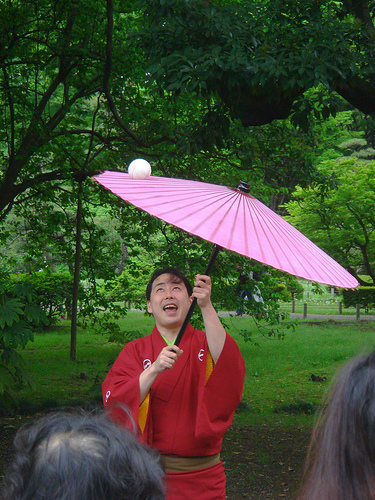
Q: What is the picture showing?
A: It is showing a park.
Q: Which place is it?
A: It is a park.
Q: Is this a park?
A: Yes, it is a park.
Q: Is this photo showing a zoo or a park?
A: It is showing a park.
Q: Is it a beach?
A: No, it is a park.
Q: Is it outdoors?
A: Yes, it is outdoors.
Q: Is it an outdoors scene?
A: Yes, it is outdoors.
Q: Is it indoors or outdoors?
A: It is outdoors.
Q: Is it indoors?
A: No, it is outdoors.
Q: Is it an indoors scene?
A: No, it is outdoors.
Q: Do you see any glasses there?
A: No, there are no glasses.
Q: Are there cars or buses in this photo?
A: No, there are no cars or buses.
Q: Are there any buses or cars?
A: No, there are no cars or buses.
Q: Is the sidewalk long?
A: Yes, the sidewalk is long.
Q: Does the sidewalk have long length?
A: Yes, the sidewalk is long.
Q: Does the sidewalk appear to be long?
A: Yes, the sidewalk is long.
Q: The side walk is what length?
A: The side walk is long.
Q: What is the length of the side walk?
A: The side walk is long.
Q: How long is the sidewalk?
A: The sidewalk is long.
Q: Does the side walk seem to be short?
A: No, the side walk is long.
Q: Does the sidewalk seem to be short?
A: No, the sidewalk is long.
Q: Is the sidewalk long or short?
A: The sidewalk is long.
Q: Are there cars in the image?
A: No, there are no cars.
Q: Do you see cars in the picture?
A: No, there are no cars.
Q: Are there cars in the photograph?
A: No, there are no cars.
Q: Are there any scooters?
A: No, there are no scooters.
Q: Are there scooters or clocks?
A: No, there are no scooters or clocks.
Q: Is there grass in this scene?
A: Yes, there is grass.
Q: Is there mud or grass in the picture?
A: Yes, there is grass.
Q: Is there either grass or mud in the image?
A: Yes, there is grass.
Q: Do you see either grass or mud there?
A: Yes, there is grass.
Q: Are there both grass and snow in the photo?
A: No, there is grass but no snow.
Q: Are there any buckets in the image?
A: No, there are no buckets.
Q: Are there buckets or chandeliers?
A: No, there are no buckets or chandeliers.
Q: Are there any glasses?
A: No, there are no glasses.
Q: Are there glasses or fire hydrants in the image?
A: No, there are no glasses or fire hydrants.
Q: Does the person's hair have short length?
A: Yes, the hair is short.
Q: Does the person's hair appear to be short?
A: Yes, the hair is short.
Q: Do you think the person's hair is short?
A: Yes, the hair is short.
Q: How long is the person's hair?
A: The hair is short.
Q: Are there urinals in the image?
A: No, there are no urinals.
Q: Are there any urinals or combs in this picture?
A: No, there are no urinals or combs.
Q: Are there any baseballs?
A: Yes, there is a baseball.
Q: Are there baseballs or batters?
A: Yes, there is a baseball.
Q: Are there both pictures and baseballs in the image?
A: No, there is a baseball but no pictures.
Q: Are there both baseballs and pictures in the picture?
A: No, there is a baseball but no pictures.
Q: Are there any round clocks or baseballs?
A: Yes, there is a round baseball.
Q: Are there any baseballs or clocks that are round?
A: Yes, the baseball is round.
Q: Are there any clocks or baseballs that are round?
A: Yes, the baseball is round.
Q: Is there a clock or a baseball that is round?
A: Yes, the baseball is round.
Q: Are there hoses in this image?
A: No, there are no hoses.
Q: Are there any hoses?
A: No, there are no hoses.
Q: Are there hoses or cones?
A: No, there are no hoses or cones.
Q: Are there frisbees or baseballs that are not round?
A: No, there is a baseball but it is round.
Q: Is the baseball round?
A: Yes, the baseball is round.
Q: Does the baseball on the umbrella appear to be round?
A: Yes, the baseball is round.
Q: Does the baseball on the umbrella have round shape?
A: Yes, the baseball is round.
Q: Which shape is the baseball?
A: The baseball is round.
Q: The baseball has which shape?
A: The baseball is round.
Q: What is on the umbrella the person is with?
A: The baseball is on the umbrella.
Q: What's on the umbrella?
A: The baseball is on the umbrella.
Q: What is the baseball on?
A: The baseball is on the umbrella.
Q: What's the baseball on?
A: The baseball is on the umbrella.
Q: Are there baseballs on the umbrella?
A: Yes, there is a baseball on the umbrella.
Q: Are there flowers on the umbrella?
A: No, there is a baseball on the umbrella.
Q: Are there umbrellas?
A: Yes, there is an umbrella.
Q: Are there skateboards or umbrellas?
A: Yes, there is an umbrella.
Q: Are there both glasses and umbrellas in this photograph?
A: No, there is an umbrella but no glasses.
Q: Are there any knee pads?
A: No, there are no knee pads.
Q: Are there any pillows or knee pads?
A: No, there are no knee pads or pillows.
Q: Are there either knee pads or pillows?
A: No, there are no knee pads or pillows.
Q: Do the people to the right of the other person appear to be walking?
A: Yes, the people are walking.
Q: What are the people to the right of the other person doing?
A: The people are walking.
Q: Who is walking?
A: The people are walking.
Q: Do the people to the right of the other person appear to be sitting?
A: No, the people are walking.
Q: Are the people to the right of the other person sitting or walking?
A: The people are walking.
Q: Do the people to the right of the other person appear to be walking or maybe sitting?
A: The people are walking.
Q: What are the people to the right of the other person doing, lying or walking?
A: The people are walking.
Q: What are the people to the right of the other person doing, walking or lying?
A: The people are walking.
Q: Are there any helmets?
A: No, there are no helmets.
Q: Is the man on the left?
A: Yes, the man is on the left of the image.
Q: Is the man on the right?
A: No, the man is on the left of the image.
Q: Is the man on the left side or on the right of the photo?
A: The man is on the left of the image.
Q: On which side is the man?
A: The man is on the left of the image.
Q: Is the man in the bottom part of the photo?
A: Yes, the man is in the bottom of the image.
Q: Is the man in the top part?
A: No, the man is in the bottom of the image.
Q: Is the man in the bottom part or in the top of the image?
A: The man is in the bottom of the image.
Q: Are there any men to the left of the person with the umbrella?
A: Yes, there is a man to the left of the person.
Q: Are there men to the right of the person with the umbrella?
A: No, the man is to the left of the person.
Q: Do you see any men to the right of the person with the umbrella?
A: No, the man is to the left of the person.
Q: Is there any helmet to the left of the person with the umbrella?
A: No, there is a man to the left of the person.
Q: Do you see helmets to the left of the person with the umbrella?
A: No, there is a man to the left of the person.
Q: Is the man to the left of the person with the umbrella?
A: Yes, the man is to the left of the person.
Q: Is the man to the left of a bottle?
A: No, the man is to the left of the person.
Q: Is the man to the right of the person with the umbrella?
A: No, the man is to the left of the person.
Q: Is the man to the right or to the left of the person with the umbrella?
A: The man is to the left of the person.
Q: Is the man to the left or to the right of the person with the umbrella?
A: The man is to the left of the person.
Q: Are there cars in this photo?
A: No, there are no cars.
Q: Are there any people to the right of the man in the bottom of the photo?
A: Yes, there is a person to the right of the man.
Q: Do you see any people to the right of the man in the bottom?
A: Yes, there is a person to the right of the man.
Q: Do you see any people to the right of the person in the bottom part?
A: Yes, there is a person to the right of the man.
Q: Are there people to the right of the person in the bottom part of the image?
A: Yes, there is a person to the right of the man.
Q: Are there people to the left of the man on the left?
A: No, the person is to the right of the man.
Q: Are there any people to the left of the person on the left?
A: No, the person is to the right of the man.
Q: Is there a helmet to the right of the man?
A: No, there is a person to the right of the man.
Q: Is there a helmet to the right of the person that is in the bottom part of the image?
A: No, there is a person to the right of the man.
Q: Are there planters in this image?
A: No, there are no planters.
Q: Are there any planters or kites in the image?
A: No, there are no planters or kites.